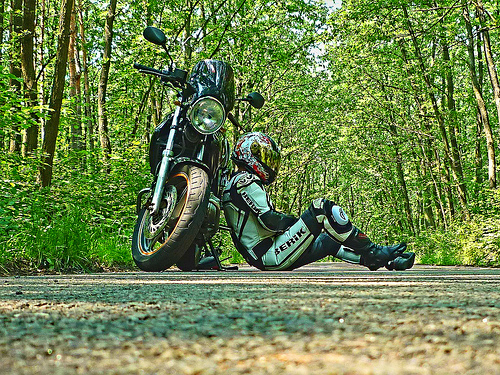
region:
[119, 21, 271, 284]
shiny black motor bike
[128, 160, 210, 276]
black rubber tire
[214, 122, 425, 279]
sitting motor bike driver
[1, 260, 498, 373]
brown gravel covered road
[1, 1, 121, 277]
small grouping of tall trees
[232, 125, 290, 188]
red and black helmet with a yellow lens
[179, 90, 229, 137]
large shiny head light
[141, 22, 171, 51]
right side rear view mirror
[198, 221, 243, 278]
black metal painted kick stand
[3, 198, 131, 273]
tall blades of green grass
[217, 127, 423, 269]
Man is leaning against motorcycle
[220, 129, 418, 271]
Man is sitting on the ground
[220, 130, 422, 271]
Man is sitting on asphalt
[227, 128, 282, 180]
Man is wearing a helmet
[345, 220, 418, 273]
Man is wearing boots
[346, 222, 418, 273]
Man is wearing black boots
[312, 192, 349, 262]
Man is wearing knee pads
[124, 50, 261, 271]
Motorcycle is parked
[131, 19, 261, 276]
Black motorcycle is parked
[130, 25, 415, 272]
Man is leaning against black motorcycle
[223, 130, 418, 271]
a bike racer wearing his helmet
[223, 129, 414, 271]
bike racer is sitting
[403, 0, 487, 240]
trees with green leaves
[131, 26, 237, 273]
black color bike parked with its side stand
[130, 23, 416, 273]
bike racer is sitting near his bike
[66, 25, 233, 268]
bike is parked near the trees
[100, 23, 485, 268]
bike racer is sitting in a forest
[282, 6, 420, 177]
leaves of the trees almost covering the sky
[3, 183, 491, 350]
a path inside the forest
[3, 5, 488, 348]
trees grown on both side of the path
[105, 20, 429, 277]
A person leaning against their parked motorcycle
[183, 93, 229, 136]
The motorcycle's headlight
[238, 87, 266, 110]
The motorcycle's left mirror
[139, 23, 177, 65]
The motorcycle's right mirror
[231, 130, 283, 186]
The motorcyclist's helmet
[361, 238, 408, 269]
The motorcylist's right foot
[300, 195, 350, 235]
the motorcyclist's right knee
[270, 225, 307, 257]
A logo on the motorcyclist's pants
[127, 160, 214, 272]
the motorcycle's front wheel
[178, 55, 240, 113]
the motorcycle's windshield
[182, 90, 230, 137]
The headlight of the motorcycle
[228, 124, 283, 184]
The motorcyclist's helmet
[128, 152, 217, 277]
The front wheel of the motorcycle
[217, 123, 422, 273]
A motorcyclist sitting by the motorcycle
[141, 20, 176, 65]
The right mirror of the motorcycle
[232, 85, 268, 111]
The left mirror of the motorcycle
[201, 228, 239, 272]
The kick stand of the motorcycle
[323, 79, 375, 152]
Part of the green trees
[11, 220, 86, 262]
A green grass on the side of the road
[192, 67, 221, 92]
Part of the black motorcycle